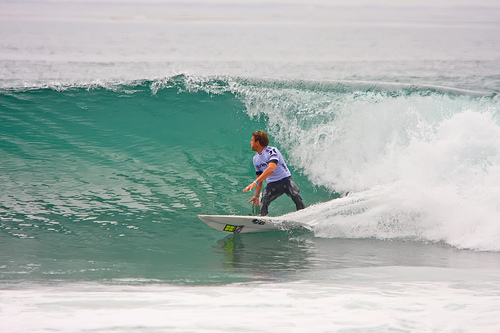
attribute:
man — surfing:
[252, 127, 299, 237]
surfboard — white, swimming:
[194, 209, 295, 223]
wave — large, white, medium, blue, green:
[347, 108, 447, 227]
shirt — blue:
[251, 151, 297, 181]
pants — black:
[257, 183, 312, 211]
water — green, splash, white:
[31, 115, 256, 207]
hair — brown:
[259, 133, 267, 143]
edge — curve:
[80, 74, 171, 94]